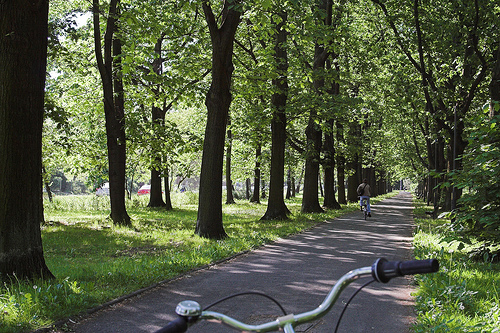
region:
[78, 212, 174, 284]
The grass is green and tall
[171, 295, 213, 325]
The bike has a bell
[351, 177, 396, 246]
The person is riding a bike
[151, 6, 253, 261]
The tree is tall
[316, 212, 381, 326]
The path is gravel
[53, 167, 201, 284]
The sun is shining through the trees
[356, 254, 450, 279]
The handle bars are black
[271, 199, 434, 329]
The path has shadows on it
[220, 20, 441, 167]
The leaves are green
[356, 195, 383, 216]
The person is wearing jeans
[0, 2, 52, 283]
large brown thick stem in the left side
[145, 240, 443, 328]
grey bicycle handlebars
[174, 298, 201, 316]
grey bell in bicycle handlebars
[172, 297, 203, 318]
small grey bell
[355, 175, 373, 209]
man riding a bike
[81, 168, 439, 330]
large bike path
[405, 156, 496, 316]
small green grass in the right side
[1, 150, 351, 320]
small green grass in the left side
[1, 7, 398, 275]
bunch of trees in a park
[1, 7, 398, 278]
bunch of large brown stems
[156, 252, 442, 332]
Bicycle handle bars up front.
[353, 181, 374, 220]
Person on bicycle far away.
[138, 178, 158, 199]
Red building off in the distance.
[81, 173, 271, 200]
Buildings in the background.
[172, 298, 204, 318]
Bell on the handle bars.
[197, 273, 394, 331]
Brake wires on the handle bars.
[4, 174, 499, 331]
Lots of green foliage along the path.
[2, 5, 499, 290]
Tall trees following the trail.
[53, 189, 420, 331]
Long trail for bikes.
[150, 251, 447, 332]
Black handles on the handle bars.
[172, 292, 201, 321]
small silver bicycle bell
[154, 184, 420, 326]
black asphalt path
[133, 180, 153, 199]
tail end of red vehicle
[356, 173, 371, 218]
person riding bike down path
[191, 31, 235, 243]
tall tree trunk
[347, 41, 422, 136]
green leaves on trees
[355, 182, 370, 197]
black carry on bag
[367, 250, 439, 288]
black plastic handle bar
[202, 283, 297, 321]
black bicycle brake wire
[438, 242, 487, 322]
gree grass on side of road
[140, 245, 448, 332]
the handlebars of a bicycle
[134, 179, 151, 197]
a red tent visible through the trees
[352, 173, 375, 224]
a person riding a bike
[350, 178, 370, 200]
a bag on a person's back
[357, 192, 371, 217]
blue jeans on a person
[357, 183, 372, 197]
a gray shirt on a person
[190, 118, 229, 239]
the dark brown trunk of a tree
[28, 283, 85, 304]
flowers along the side of the road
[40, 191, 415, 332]
a long narrow road through the trees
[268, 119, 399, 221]
a row of trees along a road